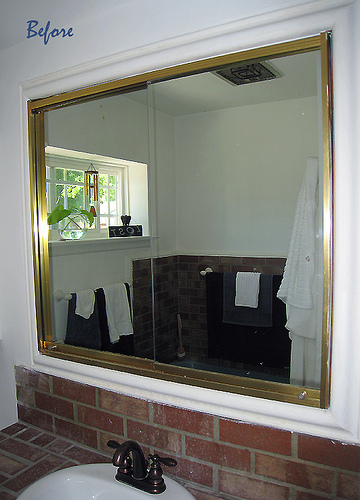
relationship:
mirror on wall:
[27, 27, 333, 410] [0, 0, 359, 445]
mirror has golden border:
[27, 27, 333, 410] [32, 31, 331, 412]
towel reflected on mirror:
[232, 273, 261, 313] [27, 27, 333, 410]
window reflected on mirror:
[44, 149, 149, 238] [27, 27, 333, 410]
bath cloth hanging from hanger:
[273, 149, 319, 312] [305, 154, 320, 165]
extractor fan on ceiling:
[210, 62, 288, 89] [0, 0, 321, 118]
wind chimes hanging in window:
[84, 162, 99, 202] [44, 149, 149, 238]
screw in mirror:
[297, 388, 308, 404] [27, 27, 333, 410]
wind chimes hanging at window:
[84, 162, 99, 202] [44, 149, 149, 238]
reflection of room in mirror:
[32, 47, 321, 395] [27, 27, 333, 410]